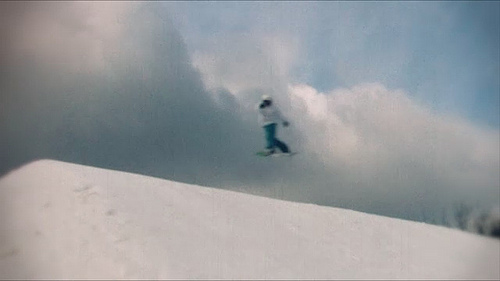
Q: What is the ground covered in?
A: Snow.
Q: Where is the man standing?
A: Snow mountain.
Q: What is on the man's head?
A: Hat.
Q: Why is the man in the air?
A: Snow jumping.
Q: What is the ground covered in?
A: Snow.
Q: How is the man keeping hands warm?
A: Gloves.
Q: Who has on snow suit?
A: A man.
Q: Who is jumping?
A: The skier.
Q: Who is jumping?
A: A man.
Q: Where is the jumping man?
A: In the air.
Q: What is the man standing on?
A: A snowboard.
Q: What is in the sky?
A: Clouds.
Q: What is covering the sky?
A: Clouds.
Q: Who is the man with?
A: No one.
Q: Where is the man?
A: On the mountain.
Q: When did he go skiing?
A: During the day.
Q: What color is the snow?
A: White.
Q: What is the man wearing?
A: Ski clothes.